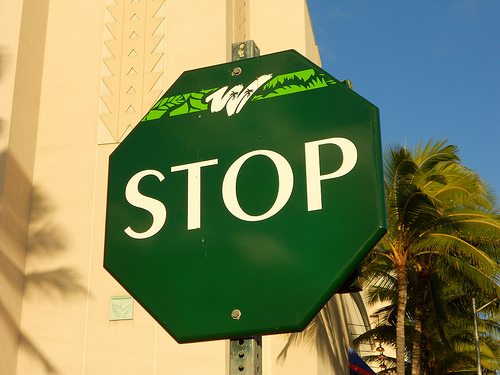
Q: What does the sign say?
A: STOP.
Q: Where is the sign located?
A: In front of palm trees.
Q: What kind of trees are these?
A: Palm trees.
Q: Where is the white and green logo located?
A: On green sign above STOP.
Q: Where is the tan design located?
A: On the side of the building.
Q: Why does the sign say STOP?
A: So people will stop before proceeding.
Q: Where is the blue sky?
A: Above the trees.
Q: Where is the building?
A: Next to the trees.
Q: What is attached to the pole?
A: A stop sign.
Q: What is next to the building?
A: Palm trees.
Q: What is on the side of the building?
A: A shadow of a tree.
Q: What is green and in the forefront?
A: A stop sign.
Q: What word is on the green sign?
A: Stop.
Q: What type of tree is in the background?
A: A palm tree.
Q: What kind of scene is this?
A: Tropical.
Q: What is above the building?
A: The clear sky.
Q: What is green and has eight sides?
A: The stop sign.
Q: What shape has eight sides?
A: Octagons.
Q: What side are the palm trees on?
A: Right.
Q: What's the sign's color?
A: Green.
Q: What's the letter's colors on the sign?
A: White.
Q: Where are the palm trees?
A: Behind the sign.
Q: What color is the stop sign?
A: Green and white.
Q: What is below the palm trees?
A: Flag.